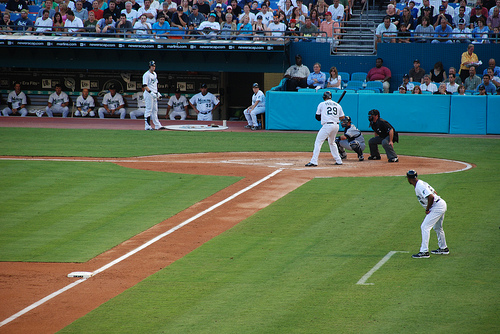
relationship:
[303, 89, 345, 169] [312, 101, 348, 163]
baseball player wearing uniform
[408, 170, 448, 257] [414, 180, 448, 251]
baseball player wearing uniform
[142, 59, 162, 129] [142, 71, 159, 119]
baseball player wearing uniform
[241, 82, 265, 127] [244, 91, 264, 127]
baseball player wearing uniform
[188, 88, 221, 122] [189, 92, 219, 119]
baseball player wearing uniform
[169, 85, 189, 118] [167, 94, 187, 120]
baseball player wearing uniform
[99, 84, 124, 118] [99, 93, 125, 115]
baseball player wearing uniform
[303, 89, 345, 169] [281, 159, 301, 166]
baseball player at plate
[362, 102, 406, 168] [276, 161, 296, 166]
umpire crouched behind plate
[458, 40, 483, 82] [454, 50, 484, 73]
man in shirt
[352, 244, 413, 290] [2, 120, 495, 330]
lines painted on grass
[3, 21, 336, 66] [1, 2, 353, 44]
rails in front of crowd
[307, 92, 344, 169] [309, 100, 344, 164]
baseball player in a uniform